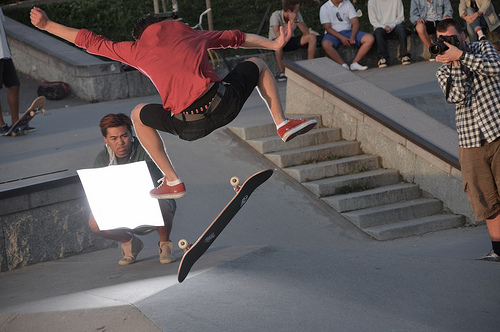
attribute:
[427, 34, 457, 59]
camera — black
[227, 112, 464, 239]
stairs — concrete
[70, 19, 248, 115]
shirt — red, long sleeved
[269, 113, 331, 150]
sneakers — red, white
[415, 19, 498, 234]
camera — black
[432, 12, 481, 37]
hair — dark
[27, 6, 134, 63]
arm — extended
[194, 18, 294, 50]
arm — extended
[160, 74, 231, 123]
belt — gray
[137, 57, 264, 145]
shorts — black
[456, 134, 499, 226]
shorts — black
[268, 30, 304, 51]
shorts — black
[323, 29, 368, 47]
shorts — black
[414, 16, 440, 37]
shorts — black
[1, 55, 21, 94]
shorts — black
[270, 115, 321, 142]
shoe — red and white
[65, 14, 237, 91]
shirt — red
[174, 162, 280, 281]
skateboard — upside down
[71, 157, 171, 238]
paper — white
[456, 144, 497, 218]
shorts — brown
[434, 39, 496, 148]
shirt — squared , black, white, plaid